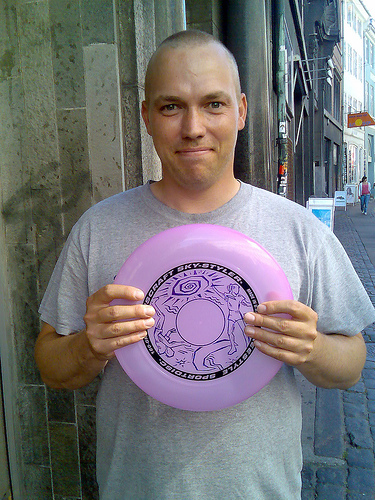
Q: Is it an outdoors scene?
A: Yes, it is outdoors.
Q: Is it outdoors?
A: Yes, it is outdoors.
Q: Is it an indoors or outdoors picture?
A: It is outdoors.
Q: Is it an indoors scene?
A: No, it is outdoors.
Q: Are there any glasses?
A: No, there are no glasses.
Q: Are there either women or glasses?
A: Yes, there is a woman.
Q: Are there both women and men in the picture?
A: Yes, there are both a woman and a man.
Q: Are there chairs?
A: No, there are no chairs.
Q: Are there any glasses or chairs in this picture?
A: No, there are no chairs or glasses.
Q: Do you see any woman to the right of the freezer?
A: Yes, there is a woman to the right of the freezer.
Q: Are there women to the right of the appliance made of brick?
A: Yes, there is a woman to the right of the freezer.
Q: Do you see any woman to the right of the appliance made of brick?
A: Yes, there is a woman to the right of the freezer.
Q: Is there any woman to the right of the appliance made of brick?
A: Yes, there is a woman to the right of the freezer.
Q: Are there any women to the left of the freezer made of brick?
A: No, the woman is to the right of the freezer.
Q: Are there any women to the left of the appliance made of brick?
A: No, the woman is to the right of the freezer.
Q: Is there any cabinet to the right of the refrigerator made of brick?
A: No, there is a woman to the right of the refrigerator.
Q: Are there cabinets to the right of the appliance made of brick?
A: No, there is a woman to the right of the refrigerator.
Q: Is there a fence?
A: No, there are no fences.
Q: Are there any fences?
A: No, there are no fences.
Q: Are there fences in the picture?
A: No, there are no fences.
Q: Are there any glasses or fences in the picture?
A: No, there are no fences or glasses.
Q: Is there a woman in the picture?
A: Yes, there is a woman.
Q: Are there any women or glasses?
A: Yes, there is a woman.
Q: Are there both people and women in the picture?
A: Yes, there are both a woman and a person.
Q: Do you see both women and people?
A: Yes, there are both a woman and a person.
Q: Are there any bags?
A: No, there are no bags.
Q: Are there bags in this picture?
A: No, there are no bags.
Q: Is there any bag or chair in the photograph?
A: No, there are no bags or chairs.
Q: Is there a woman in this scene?
A: Yes, there is a woman.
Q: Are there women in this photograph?
A: Yes, there is a woman.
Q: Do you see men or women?
A: Yes, there is a woman.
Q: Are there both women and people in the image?
A: Yes, there are both a woman and a person.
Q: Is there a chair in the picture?
A: No, there are no chairs.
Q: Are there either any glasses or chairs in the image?
A: No, there are no chairs or glasses.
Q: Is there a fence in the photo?
A: No, there are no fences.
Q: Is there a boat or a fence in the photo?
A: No, there are no fences or boats.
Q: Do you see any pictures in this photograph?
A: No, there are no pictures.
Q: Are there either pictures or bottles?
A: No, there are no pictures or bottles.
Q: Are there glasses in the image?
A: No, there are no glasses.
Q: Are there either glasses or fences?
A: No, there are no glasses or fences.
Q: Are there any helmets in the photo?
A: No, there are no helmets.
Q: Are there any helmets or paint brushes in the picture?
A: No, there are no helmets or paint brushes.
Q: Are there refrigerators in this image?
A: Yes, there is a refrigerator.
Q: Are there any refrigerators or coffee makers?
A: Yes, there is a refrigerator.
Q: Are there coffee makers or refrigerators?
A: Yes, there is a refrigerator.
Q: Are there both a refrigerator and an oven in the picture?
A: No, there is a refrigerator but no ovens.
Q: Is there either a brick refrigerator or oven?
A: Yes, there is a brick refrigerator.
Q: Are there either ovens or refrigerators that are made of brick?
A: Yes, the refrigerator is made of brick.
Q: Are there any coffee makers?
A: No, there are no coffee makers.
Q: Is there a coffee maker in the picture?
A: No, there are no coffee makers.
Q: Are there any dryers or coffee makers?
A: No, there are no coffee makers or dryers.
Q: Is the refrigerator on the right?
A: Yes, the refrigerator is on the right of the image.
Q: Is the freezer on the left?
A: No, the freezer is on the right of the image.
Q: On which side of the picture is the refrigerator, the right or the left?
A: The refrigerator is on the right of the image.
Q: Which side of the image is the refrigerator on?
A: The refrigerator is on the right of the image.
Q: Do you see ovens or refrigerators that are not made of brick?
A: No, there is a refrigerator but it is made of brick.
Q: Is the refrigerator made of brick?
A: Yes, the refrigerator is made of brick.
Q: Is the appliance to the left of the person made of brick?
A: Yes, the refrigerator is made of brick.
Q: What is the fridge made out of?
A: The fridge is made of brick.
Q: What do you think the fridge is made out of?
A: The fridge is made of brick.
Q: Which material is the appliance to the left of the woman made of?
A: The fridge is made of brick.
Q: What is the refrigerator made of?
A: The fridge is made of brick.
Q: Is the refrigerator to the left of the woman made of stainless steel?
A: No, the freezer is made of brick.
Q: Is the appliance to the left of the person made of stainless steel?
A: No, the freezer is made of brick.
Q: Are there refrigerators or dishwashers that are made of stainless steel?
A: No, there is a refrigerator but it is made of brick.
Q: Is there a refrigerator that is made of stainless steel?
A: No, there is a refrigerator but it is made of brick.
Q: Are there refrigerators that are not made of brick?
A: No, there is a refrigerator but it is made of brick.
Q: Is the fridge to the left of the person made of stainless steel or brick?
A: The freezer is made of brick.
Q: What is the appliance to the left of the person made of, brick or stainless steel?
A: The freezer is made of brick.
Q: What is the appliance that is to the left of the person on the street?
A: The appliance is a refrigerator.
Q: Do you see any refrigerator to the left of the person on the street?
A: Yes, there is a refrigerator to the left of the person.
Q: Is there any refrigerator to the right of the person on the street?
A: No, the refrigerator is to the left of the person.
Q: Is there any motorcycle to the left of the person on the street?
A: No, there is a refrigerator to the left of the person.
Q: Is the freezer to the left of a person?
A: Yes, the freezer is to the left of a person.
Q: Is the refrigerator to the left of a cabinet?
A: No, the refrigerator is to the left of a person.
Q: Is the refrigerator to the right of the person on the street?
A: No, the refrigerator is to the left of the person.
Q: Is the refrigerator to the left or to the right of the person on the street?
A: The refrigerator is to the left of the person.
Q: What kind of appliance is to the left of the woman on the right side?
A: The appliance is a refrigerator.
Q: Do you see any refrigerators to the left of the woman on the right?
A: Yes, there is a refrigerator to the left of the woman.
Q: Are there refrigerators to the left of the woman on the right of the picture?
A: Yes, there is a refrigerator to the left of the woman.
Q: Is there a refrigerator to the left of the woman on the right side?
A: Yes, there is a refrigerator to the left of the woman.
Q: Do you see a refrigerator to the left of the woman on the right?
A: Yes, there is a refrigerator to the left of the woman.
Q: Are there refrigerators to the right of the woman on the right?
A: No, the refrigerator is to the left of the woman.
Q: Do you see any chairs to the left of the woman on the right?
A: No, there is a refrigerator to the left of the woman.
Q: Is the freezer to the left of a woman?
A: Yes, the freezer is to the left of a woman.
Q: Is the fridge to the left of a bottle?
A: No, the fridge is to the left of a woman.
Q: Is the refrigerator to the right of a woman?
A: No, the refrigerator is to the left of a woman.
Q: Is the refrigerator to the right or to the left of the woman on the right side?
A: The refrigerator is to the left of the woman.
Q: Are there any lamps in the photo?
A: No, there are no lamps.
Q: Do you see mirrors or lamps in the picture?
A: No, there are no lamps or mirrors.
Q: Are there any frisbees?
A: Yes, there is a frisbee.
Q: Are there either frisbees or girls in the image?
A: Yes, there is a frisbee.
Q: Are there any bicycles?
A: No, there are no bicycles.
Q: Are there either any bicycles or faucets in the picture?
A: No, there are no bicycles or faucets.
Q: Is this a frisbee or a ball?
A: This is a frisbee.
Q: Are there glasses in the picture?
A: No, there are no glasses.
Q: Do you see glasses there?
A: No, there are no glasses.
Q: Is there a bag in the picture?
A: No, there are no bags.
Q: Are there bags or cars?
A: No, there are no bags or cars.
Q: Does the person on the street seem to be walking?
A: Yes, the person is walking.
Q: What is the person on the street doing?
A: The person is walking.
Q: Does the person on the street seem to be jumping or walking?
A: The person is walking.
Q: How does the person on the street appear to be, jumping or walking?
A: The person is walking.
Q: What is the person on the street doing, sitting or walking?
A: The person is walking.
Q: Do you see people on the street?
A: Yes, there is a person on the street.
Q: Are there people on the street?
A: Yes, there is a person on the street.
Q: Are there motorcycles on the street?
A: No, there is a person on the street.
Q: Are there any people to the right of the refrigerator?
A: Yes, there is a person to the right of the refrigerator.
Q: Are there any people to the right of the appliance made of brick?
A: Yes, there is a person to the right of the refrigerator.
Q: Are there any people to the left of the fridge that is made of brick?
A: No, the person is to the right of the refrigerator.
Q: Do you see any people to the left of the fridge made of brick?
A: No, the person is to the right of the refrigerator.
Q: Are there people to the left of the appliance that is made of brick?
A: No, the person is to the right of the refrigerator.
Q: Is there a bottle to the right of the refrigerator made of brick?
A: No, there is a person to the right of the refrigerator.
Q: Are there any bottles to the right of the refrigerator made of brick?
A: No, there is a person to the right of the refrigerator.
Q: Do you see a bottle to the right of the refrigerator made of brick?
A: No, there is a person to the right of the refrigerator.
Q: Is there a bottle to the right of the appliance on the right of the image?
A: No, there is a person to the right of the refrigerator.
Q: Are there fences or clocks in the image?
A: No, there are no fences or clocks.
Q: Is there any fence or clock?
A: No, there are no fences or clocks.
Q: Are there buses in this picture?
A: No, there are no buses.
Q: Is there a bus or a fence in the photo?
A: No, there are no buses or fences.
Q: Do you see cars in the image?
A: No, there are no cars.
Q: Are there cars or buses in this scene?
A: No, there are no cars or buses.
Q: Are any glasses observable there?
A: No, there are no glasses.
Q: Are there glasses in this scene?
A: No, there are no glasses.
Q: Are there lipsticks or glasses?
A: No, there are no glasses or lipsticks.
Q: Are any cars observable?
A: No, there are no cars.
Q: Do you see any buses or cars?
A: No, there are no cars or buses.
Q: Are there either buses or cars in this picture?
A: No, there are no cars or buses.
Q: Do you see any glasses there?
A: No, there are no glasses.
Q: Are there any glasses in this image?
A: No, there are no glasses.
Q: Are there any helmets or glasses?
A: No, there are no glasses or helmets.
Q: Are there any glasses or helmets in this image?
A: No, there are no glasses or helmets.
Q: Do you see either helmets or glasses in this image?
A: No, there are no glasses or helmets.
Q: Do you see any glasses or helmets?
A: No, there are no glasses or helmets.